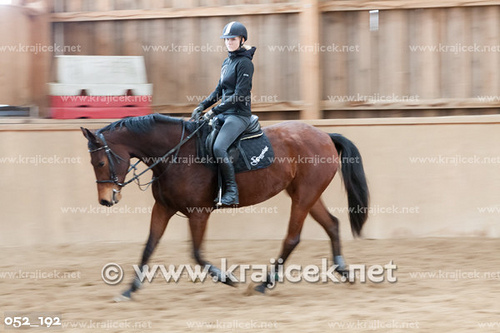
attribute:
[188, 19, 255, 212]
girl — sitting, riding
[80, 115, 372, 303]
horse — in motion, a, brown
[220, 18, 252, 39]
helmet — black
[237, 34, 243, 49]
strip — black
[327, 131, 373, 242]
tail — black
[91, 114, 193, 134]
mane — black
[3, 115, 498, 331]
floor — brown, sandy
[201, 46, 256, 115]
jacket — black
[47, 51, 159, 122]
cooler — white, red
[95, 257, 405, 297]
watermark — copyright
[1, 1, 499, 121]
fence — wooden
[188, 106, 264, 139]
saddle — black